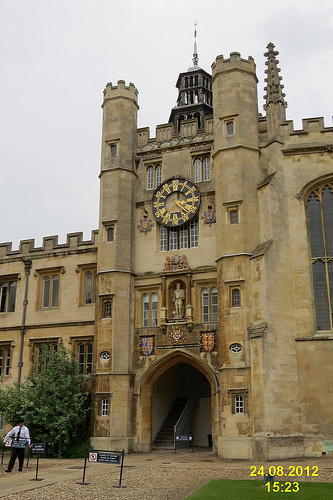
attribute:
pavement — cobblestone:
[0, 450, 332, 499]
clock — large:
[146, 176, 229, 232]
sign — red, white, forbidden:
[85, 449, 120, 464]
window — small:
[227, 388, 246, 417]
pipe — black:
[14, 282, 28, 390]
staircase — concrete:
[152, 391, 195, 449]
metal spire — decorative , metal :
[186, 20, 200, 66]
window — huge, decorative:
[301, 171, 331, 332]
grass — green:
[183, 475, 331, 498]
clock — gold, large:
[150, 176, 200, 226]